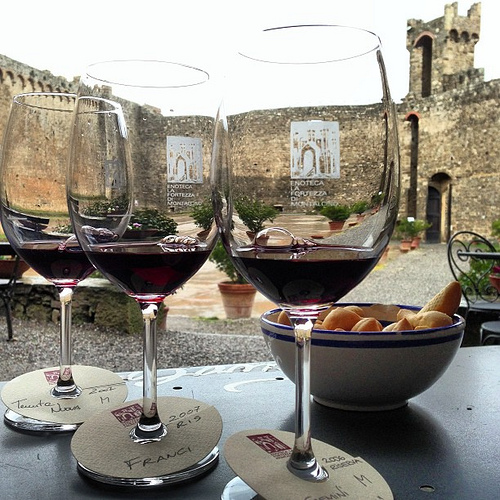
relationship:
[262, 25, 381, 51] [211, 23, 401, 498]
mouth of glass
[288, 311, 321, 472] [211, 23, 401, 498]
stem of glass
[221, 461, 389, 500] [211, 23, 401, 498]
base of glass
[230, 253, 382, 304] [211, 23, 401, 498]
wine in glass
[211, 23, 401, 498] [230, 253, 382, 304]
glass for wine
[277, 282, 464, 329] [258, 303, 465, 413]
bread in bowl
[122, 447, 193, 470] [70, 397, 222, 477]
writing on paper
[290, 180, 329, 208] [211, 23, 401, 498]
writing on glass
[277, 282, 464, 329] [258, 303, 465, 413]
bread for bowl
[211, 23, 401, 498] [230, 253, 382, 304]
glass of wine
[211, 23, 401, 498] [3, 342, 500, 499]
glass on table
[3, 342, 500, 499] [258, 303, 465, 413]
table under bowl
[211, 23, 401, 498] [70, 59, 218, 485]
glass next to glass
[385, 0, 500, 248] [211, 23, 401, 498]
wall behind glass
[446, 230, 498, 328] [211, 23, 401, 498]
chair behind glass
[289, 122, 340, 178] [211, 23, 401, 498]
logo on glass